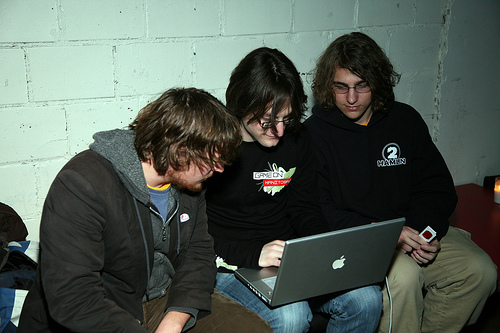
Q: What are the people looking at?
A: Macbook.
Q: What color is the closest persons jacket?
A: Grey.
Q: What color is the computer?
A: Grey.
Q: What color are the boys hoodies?
A: Black.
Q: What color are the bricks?
A: White.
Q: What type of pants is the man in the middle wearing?
A: Jeans.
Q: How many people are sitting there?
A: Three.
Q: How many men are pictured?
A: 3.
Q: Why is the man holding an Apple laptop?
A: To use.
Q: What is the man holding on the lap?
A: An Apple laptop computer.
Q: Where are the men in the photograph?
A: A dorm room.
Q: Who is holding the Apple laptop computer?
A: Man in the middle.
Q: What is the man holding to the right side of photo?
A: A cell phone.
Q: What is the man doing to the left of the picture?
A: Looking at the computer screen.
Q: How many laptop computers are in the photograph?
A: 1.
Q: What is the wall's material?
A: Bricks.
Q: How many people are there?
A: 3.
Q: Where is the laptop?
A: On the middle boy's lap.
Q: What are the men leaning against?
A: Wall.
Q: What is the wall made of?
A: Cinder block.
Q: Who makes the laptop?
A: Apple.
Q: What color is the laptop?
A: Silver.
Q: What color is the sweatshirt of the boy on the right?
A: Black.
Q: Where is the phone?
A: In the boy's hands.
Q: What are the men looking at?
A: Laptop.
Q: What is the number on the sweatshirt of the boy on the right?
A: Two.